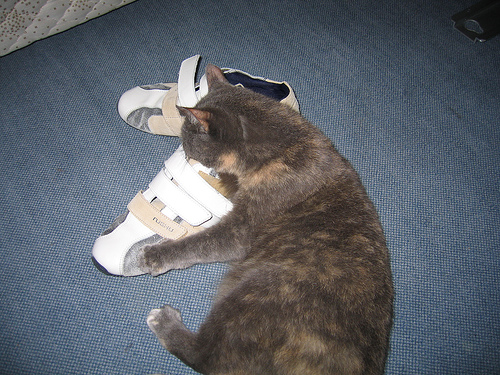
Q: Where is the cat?
A: On the ground.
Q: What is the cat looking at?
A: At a shoe.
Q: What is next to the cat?
A: A shoe.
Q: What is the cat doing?
A: Laying.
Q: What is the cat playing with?
A: A shoe.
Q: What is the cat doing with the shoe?
A: Playing.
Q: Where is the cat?
A: On the sofa.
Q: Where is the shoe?
A: Next to the cat.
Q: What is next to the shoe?
A: A cat.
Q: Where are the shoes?
A: On the floor.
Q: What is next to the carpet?
A: A quilted mattress.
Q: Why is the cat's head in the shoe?
A: The cat is playing.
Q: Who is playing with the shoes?
A: A cat.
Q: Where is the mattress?
A: On the carpet.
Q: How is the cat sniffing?
A: With the nose.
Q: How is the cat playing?
A: Half on the shoe.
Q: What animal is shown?
A: Cat.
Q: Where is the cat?
A: On the floor.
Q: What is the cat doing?
A: Playing.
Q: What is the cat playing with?
A: Shoes.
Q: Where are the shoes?
A: By the cat.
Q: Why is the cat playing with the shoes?
A: Curiosity.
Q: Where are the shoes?
A: On the floor.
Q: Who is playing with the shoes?
A: The cat.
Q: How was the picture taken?
A: With a camera.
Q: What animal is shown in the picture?
A: A cat.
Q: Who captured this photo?
A: The photographer.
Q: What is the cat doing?
A: Smelling the inside of the shoe.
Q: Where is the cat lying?
A: On the floor.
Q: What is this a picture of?
A: A cat;s face in a shoe.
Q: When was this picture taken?
A: During waking hours.